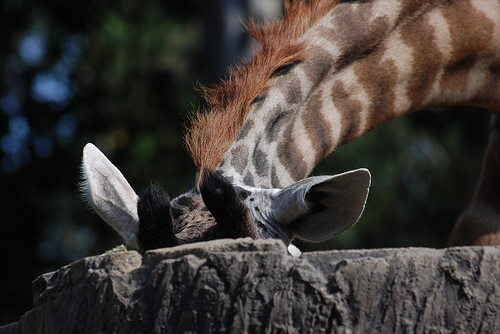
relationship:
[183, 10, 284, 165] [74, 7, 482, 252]
mane on giraffe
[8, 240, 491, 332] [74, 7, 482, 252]
wood near giraffe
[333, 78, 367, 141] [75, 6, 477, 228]
spot on giraffe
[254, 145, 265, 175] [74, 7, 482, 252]
spot on giraffe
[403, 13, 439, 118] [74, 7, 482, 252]
spot on giraffe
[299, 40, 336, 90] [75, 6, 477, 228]
spot on giraffe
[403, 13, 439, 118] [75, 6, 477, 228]
spot on giraffe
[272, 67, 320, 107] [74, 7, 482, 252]
spot on giraffe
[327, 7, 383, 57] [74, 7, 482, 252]
spot on giraffe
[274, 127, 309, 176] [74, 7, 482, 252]
spot on giraffe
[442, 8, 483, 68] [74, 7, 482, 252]
spot on giraffe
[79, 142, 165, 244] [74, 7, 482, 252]
ear of giraffe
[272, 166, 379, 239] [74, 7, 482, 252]
ear of giraffe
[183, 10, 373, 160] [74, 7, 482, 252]
mane of giraffe